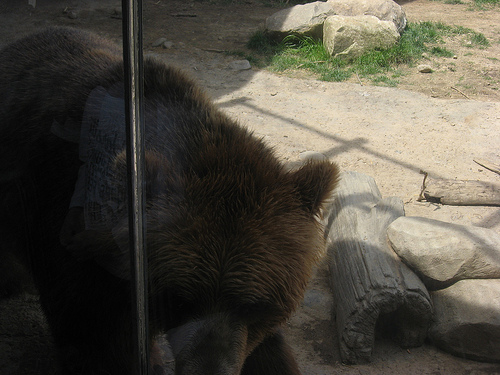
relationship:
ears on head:
[97, 121, 353, 228] [86, 127, 334, 360]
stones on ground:
[239, 2, 410, 49] [131, 5, 499, 242]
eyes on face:
[168, 275, 279, 330] [86, 127, 334, 360]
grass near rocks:
[245, 19, 467, 101] [321, 13, 400, 59]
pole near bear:
[108, 0, 161, 366] [0, 30, 329, 374]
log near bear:
[298, 151, 447, 359] [0, 30, 329, 374]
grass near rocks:
[245, 19, 467, 101] [239, 2, 410, 49]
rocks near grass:
[239, 2, 410, 49] [245, 19, 467, 101]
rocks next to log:
[404, 172, 500, 360] [298, 151, 447, 359]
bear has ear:
[0, 30, 329, 374] [97, 121, 353, 228]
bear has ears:
[0, 30, 329, 374] [97, 121, 353, 228]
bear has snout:
[0, 30, 329, 374] [150, 303, 257, 374]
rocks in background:
[258, 6, 401, 76] [186, 6, 499, 136]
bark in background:
[408, 147, 499, 209] [186, 6, 499, 136]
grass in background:
[245, 19, 467, 101] [186, 6, 499, 136]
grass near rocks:
[245, 19, 467, 101] [258, 6, 401, 76]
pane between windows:
[108, 0, 161, 366] [19, 8, 470, 362]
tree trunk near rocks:
[298, 151, 447, 359] [404, 172, 500, 360]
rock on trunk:
[382, 196, 471, 292] [298, 151, 447, 359]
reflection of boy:
[68, 63, 228, 357] [59, 18, 206, 220]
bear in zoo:
[0, 30, 329, 374] [1, 0, 494, 370]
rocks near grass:
[258, 6, 401, 76] [245, 19, 467, 101]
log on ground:
[298, 151, 447, 359] [131, 5, 499, 242]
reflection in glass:
[68, 63, 228, 357] [19, 8, 470, 362]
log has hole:
[298, 151, 447, 359] [342, 280, 432, 362]